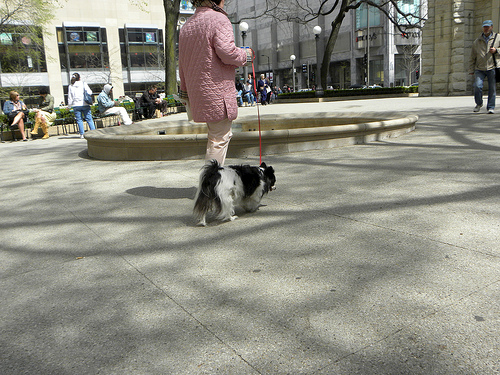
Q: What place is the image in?
A: It is at the park.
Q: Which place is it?
A: It is a park.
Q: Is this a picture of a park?
A: Yes, it is showing a park.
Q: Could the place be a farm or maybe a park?
A: It is a park.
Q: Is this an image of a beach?
A: No, the picture is showing a park.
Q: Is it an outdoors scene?
A: Yes, it is outdoors.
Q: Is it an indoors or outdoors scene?
A: It is outdoors.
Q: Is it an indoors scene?
A: No, it is outdoors.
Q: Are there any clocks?
A: No, there are no clocks.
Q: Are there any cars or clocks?
A: No, there are no clocks or cars.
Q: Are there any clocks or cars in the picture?
A: No, there are no clocks or cars.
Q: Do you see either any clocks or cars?
A: No, there are no clocks or cars.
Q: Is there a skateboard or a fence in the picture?
A: No, there are no fences or skateboards.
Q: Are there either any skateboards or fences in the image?
A: No, there are no fences or skateboards.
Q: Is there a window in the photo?
A: Yes, there is a window.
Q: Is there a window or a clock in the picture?
A: Yes, there is a window.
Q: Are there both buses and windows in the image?
A: No, there is a window but no buses.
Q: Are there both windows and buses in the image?
A: No, there is a window but no buses.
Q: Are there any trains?
A: No, there are no trains.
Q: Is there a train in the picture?
A: No, there are no trains.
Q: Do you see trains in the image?
A: No, there are no trains.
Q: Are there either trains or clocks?
A: No, there are no trains or clocks.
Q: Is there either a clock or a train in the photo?
A: No, there are no trains or clocks.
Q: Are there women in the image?
A: Yes, there is a woman.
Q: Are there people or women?
A: Yes, there is a woman.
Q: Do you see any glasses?
A: No, there are no glasses.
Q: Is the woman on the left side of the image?
A: Yes, the woman is on the left of the image.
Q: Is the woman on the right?
A: No, the woman is on the left of the image.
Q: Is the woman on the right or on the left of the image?
A: The woman is on the left of the image.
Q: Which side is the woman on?
A: The woman is on the left of the image.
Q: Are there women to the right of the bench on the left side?
A: Yes, there is a woman to the right of the bench.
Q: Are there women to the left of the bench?
A: No, the woman is to the right of the bench.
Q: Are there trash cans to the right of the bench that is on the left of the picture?
A: No, there is a woman to the right of the bench.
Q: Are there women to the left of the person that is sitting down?
A: Yes, there is a woman to the left of the person.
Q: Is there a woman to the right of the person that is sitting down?
A: No, the woman is to the left of the person.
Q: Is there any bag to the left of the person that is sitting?
A: No, there is a woman to the left of the person.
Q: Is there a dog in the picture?
A: Yes, there is a dog.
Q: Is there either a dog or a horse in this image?
A: Yes, there is a dog.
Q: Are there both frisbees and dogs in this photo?
A: No, there is a dog but no frisbees.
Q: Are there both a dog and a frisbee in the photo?
A: No, there is a dog but no frisbees.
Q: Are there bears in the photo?
A: No, there are no bears.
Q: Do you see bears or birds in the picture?
A: No, there are no bears or birds.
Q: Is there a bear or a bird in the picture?
A: No, there are no bears or birds.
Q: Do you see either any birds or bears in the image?
A: No, there are no bears or birds.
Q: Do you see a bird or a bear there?
A: No, there are no bears or birds.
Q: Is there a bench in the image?
A: Yes, there is a bench.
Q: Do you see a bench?
A: Yes, there is a bench.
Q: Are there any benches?
A: Yes, there is a bench.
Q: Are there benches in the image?
A: Yes, there is a bench.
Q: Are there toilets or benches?
A: Yes, there is a bench.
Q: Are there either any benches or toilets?
A: Yes, there is a bench.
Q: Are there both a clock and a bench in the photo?
A: No, there is a bench but no clocks.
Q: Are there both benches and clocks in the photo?
A: No, there is a bench but no clocks.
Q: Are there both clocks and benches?
A: No, there is a bench but no clocks.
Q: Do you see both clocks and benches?
A: No, there is a bench but no clocks.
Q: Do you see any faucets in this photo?
A: No, there are no faucets.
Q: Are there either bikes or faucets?
A: No, there are no faucets or bikes.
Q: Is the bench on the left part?
A: Yes, the bench is on the left of the image.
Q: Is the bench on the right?
A: No, the bench is on the left of the image.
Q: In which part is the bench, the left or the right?
A: The bench is on the left of the image.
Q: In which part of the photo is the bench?
A: The bench is on the left of the image.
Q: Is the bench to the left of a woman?
A: Yes, the bench is to the left of a woman.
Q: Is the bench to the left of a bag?
A: No, the bench is to the left of a woman.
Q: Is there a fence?
A: No, there are no fences.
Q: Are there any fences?
A: No, there are no fences.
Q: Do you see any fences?
A: No, there are no fences.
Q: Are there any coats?
A: Yes, there is a coat.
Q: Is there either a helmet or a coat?
A: Yes, there is a coat.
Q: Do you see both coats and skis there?
A: No, there is a coat but no skis.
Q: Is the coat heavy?
A: Yes, the coat is heavy.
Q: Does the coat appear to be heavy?
A: Yes, the coat is heavy.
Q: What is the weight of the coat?
A: The coat is heavy.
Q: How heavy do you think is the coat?
A: The coat is heavy.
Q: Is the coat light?
A: No, the coat is heavy.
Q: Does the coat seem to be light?
A: No, the coat is heavy.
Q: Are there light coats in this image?
A: No, there is a coat but it is heavy.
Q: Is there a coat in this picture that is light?
A: No, there is a coat but it is heavy.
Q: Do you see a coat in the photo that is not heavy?
A: No, there is a coat but it is heavy.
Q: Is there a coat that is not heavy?
A: No, there is a coat but it is heavy.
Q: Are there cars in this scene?
A: No, there are no cars.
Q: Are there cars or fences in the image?
A: No, there are no cars or fences.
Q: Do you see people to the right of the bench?
A: Yes, there is a person to the right of the bench.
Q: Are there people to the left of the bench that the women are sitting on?
A: No, the person is to the right of the bench.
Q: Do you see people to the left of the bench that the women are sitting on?
A: No, the person is to the right of the bench.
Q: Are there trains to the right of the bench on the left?
A: No, there is a person to the right of the bench.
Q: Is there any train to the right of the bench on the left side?
A: No, there is a person to the right of the bench.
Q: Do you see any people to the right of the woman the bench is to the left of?
A: Yes, there is a person to the right of the woman.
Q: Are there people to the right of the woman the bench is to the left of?
A: Yes, there is a person to the right of the woman.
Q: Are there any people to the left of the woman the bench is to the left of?
A: No, the person is to the right of the woman.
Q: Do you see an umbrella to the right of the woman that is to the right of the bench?
A: No, there is a person to the right of the woman.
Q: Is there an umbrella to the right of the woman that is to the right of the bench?
A: No, there is a person to the right of the woman.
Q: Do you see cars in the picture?
A: No, there are no cars.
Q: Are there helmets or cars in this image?
A: No, there are no cars or helmets.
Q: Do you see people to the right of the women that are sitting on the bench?
A: Yes, there is a person to the right of the women.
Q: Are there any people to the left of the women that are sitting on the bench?
A: No, the person is to the right of the women.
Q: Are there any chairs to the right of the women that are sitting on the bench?
A: No, there is a person to the right of the women.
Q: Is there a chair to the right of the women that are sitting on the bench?
A: No, there is a person to the right of the women.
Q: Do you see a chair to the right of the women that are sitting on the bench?
A: No, there is a person to the right of the women.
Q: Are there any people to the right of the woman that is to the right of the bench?
A: Yes, there is a person to the right of the woman.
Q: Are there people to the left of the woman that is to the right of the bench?
A: No, the person is to the right of the woman.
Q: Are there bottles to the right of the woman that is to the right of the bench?
A: No, there is a person to the right of the woman.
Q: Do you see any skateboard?
A: No, there are no skateboards.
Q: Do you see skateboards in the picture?
A: No, there are no skateboards.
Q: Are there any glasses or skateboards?
A: No, there are no skateboards or glasses.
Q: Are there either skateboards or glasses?
A: No, there are no skateboards or glasses.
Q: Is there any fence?
A: No, there are no fences.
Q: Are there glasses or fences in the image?
A: No, there are no fences or glasses.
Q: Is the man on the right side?
A: Yes, the man is on the right of the image.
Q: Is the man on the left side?
A: No, the man is on the right of the image.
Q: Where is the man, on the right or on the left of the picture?
A: The man is on the right of the image.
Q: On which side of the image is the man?
A: The man is on the right of the image.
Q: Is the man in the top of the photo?
A: Yes, the man is in the top of the image.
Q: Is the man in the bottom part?
A: No, the man is in the top of the image.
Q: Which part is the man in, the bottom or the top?
A: The man is in the top of the image.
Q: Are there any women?
A: Yes, there are women.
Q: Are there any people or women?
A: Yes, there are women.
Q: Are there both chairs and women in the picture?
A: No, there are women but no chairs.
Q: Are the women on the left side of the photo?
A: Yes, the women are on the left of the image.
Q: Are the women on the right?
A: No, the women are on the left of the image.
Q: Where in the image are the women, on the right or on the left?
A: The women are on the left of the image.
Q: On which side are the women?
A: The women are on the left of the image.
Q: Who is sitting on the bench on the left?
A: The women are sitting on the bench.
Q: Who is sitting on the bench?
A: The women are sitting on the bench.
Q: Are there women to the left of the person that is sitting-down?
A: Yes, there are women to the left of the person.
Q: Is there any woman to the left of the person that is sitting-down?
A: Yes, there are women to the left of the person.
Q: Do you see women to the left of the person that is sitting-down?
A: Yes, there are women to the left of the person.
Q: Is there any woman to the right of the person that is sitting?
A: No, the women are to the left of the person.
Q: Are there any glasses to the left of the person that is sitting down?
A: No, there are women to the left of the person.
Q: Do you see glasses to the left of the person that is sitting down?
A: No, there are women to the left of the person.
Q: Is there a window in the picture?
A: Yes, there is a window.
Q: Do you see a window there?
A: Yes, there is a window.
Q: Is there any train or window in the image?
A: Yes, there is a window.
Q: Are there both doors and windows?
A: No, there is a window but no doors.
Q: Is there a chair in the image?
A: No, there are no chairs.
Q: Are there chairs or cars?
A: No, there are no chairs or cars.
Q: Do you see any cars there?
A: No, there are no cars.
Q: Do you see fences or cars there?
A: No, there are no cars or fences.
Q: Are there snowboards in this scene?
A: No, there are no snowboards.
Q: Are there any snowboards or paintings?
A: No, there are no snowboards or paintings.